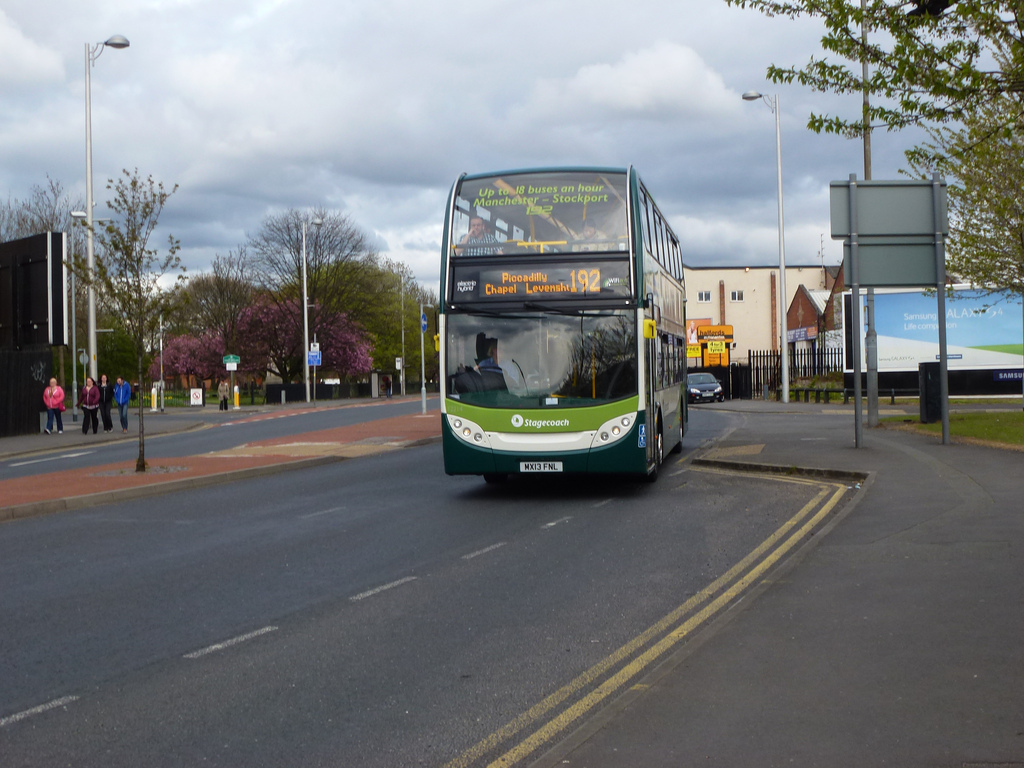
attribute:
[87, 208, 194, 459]
tree — small , green, planted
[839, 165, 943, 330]
signs — rectangular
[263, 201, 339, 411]
streetlight — metalic, off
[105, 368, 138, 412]
jacket — blue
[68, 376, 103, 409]
jacket — maroon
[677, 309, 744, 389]
signage — yellow, orange, black, street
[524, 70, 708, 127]
cloud — large, white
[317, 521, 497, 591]
marking — white, street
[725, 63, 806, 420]
pole — light, tall, gray, street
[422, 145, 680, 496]
bus — large, double decker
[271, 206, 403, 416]
tree — large, green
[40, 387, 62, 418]
jacket — pink, woman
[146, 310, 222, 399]
tree — purple, large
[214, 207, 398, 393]
tree branches — leafless